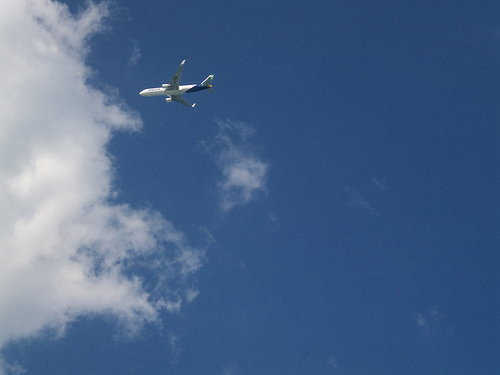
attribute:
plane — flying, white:
[130, 54, 223, 108]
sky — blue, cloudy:
[255, 15, 439, 116]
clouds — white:
[7, 16, 129, 138]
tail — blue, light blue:
[190, 73, 220, 102]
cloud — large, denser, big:
[5, 3, 124, 353]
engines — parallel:
[162, 78, 173, 108]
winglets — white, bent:
[178, 58, 199, 110]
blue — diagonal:
[189, 81, 206, 96]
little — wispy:
[222, 114, 264, 203]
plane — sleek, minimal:
[131, 51, 226, 112]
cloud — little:
[195, 108, 276, 220]